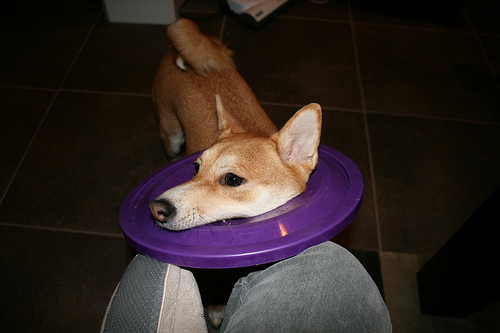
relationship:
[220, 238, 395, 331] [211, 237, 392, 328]
human wearing jeans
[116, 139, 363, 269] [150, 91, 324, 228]
frisbee holding dog's head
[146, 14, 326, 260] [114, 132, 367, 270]
dog wearing disc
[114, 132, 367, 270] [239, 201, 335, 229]
disc around neck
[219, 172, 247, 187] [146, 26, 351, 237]
eye of dog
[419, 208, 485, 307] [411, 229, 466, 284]
black leg of table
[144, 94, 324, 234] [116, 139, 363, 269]
dogs head in frisbee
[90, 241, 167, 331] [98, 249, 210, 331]
sole of shoe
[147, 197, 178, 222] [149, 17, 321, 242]
nose of dog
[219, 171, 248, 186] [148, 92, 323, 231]
eye of dog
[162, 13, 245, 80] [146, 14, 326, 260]
tail of dog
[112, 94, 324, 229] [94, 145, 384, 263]
dogs head in frisbee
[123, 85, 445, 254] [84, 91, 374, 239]
face of dog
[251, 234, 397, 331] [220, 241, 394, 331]
jeans of human